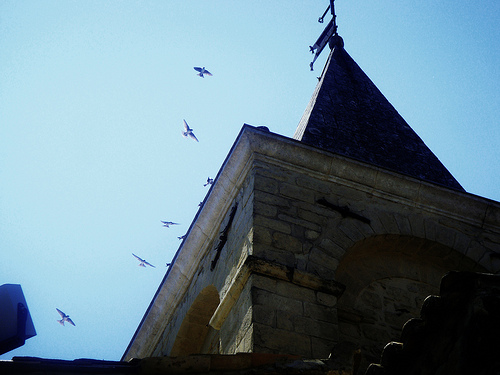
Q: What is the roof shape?
A: Pointy.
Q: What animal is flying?
A: Bird.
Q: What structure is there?
A: Building.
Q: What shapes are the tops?
A: Triangles.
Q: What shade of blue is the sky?
A: Light blue.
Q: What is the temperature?
A: 70 degrees.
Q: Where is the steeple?
A: The very top.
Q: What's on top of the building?
A: Parapet.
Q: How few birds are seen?
A: Very few.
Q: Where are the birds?
A: In the sky.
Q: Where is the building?
A: Below the birds.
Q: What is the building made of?
A: Brick.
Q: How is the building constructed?
A: Brick and mortar.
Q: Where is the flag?
A: On the top of the building.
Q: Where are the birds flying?
A: In the sky.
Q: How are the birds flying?
A: With wings.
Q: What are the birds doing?
A: Flying.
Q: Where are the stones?
A: In the building.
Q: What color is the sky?
A: Blue.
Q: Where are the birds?
A: In the sky.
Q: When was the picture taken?
A: Daytime.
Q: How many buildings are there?
A: One.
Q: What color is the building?
A: Gray.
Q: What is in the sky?
A: Birds.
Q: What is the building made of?
A: Stone.